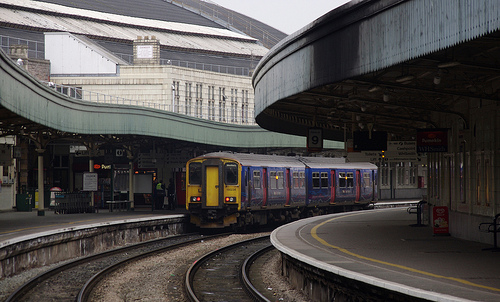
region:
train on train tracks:
[133, 92, 421, 267]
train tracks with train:
[39, 98, 311, 296]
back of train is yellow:
[172, 113, 289, 248]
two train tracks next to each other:
[46, 178, 290, 298]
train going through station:
[82, 74, 454, 296]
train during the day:
[160, 92, 405, 285]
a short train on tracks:
[172, 77, 452, 242]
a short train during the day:
[139, 78, 424, 283]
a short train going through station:
[122, 113, 405, 300]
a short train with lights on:
[147, 97, 425, 248]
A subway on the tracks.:
[190, 122, 385, 213]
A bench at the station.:
[398, 178, 427, 242]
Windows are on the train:
[256, 164, 317, 184]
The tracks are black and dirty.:
[118, 231, 263, 287]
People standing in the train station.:
[153, 168, 186, 208]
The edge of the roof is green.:
[24, 66, 241, 158]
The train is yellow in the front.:
[165, 157, 248, 229]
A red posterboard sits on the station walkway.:
[427, 192, 452, 233]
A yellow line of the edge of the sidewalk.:
[325, 221, 391, 275]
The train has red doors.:
[259, 157, 274, 207]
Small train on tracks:
[191, 152, 379, 205]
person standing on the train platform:
[149, 176, 173, 211]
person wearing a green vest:
[153, 182, 163, 191]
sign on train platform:
[80, 167, 97, 194]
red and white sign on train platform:
[92, 160, 114, 172]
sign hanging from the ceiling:
[386, 138, 418, 168]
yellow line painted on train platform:
[311, 212, 477, 294]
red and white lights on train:
[220, 189, 240, 209]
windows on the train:
[307, 173, 330, 195]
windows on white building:
[160, 77, 242, 117]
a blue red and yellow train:
[185, 151, 377, 228]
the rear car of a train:
[188, 153, 308, 228]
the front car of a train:
[307, 157, 379, 218]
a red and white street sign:
[427, 205, 452, 235]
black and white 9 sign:
[306, 126, 324, 151]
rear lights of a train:
[188, 195, 238, 206]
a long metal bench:
[55, 191, 100, 213]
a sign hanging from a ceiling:
[410, 122, 449, 152]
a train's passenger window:
[335, 171, 358, 189]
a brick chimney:
[131, 34, 160, 66]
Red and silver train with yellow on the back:
[174, 148, 400, 234]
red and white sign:
[87, 157, 114, 176]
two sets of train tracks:
[43, 227, 272, 300]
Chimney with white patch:
[133, 26, 165, 71]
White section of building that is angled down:
[38, 26, 131, 91]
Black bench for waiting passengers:
[93, 187, 137, 218]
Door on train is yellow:
[206, 165, 222, 225]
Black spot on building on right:
[288, 8, 410, 99]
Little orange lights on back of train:
[224, 192, 233, 204]